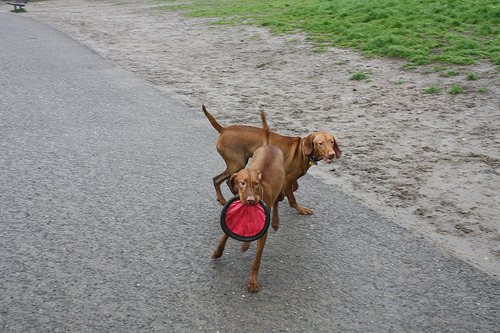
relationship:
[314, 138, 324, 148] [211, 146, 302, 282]
eye of dog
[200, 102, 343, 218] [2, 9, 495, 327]
dog walking on road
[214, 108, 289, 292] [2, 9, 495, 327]
dog walking on road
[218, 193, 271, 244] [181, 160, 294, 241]
ring on frisbee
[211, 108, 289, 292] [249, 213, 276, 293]
dog has front leg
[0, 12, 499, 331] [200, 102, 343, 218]
asphalt beneath dog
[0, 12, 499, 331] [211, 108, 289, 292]
asphalt beneath dog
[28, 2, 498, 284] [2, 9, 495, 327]
brown dirt beside road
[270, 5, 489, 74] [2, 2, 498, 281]
grass growing on ground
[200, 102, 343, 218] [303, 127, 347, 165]
dog has head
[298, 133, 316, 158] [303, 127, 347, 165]
ear on head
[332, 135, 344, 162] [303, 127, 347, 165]
ear on head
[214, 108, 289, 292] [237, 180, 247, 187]
dog has eye